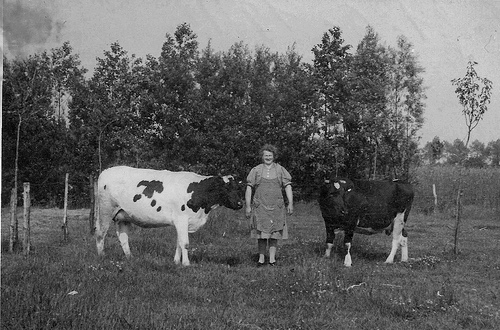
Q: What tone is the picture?
A: Black and white.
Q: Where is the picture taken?
A: A farm.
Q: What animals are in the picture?
A: Cows.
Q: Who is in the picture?
A: A woman.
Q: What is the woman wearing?
A: A dress.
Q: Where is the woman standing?
A: Between the cows.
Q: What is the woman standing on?
A: Grass.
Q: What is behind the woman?
A: Trees.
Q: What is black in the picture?
A: The right cow.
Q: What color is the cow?
A: Black and white.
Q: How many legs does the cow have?
A: Four.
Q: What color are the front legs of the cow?
A: White.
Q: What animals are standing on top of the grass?
A: Cows.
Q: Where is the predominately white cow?
A: Left of woman.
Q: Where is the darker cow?
A: Right side of woman.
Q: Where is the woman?
A: Between the cows.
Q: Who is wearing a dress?
A: The woman by the cows.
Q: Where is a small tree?
A: Right side of scene.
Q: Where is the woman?
A: Between the cows.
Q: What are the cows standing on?
A: Grass.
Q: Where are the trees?
A: Behind the woman.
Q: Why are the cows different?
A: They contain different colors and spots.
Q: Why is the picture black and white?
A: It's old.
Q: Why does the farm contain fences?
A: To protect animals from escaping.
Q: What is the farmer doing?
A: Posing for a picture.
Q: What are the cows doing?
A: Standing still.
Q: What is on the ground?
A: Grass.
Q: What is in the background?
A: Trees.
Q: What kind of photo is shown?
A: Black and white.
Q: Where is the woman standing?
A: Between two cows.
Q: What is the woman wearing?
A: A dress and an apron.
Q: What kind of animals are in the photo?
A: Cows.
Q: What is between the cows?
A: A woman.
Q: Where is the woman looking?
A: At the camera.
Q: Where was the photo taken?
A: In a field.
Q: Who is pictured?
A: A woman.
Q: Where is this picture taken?
A: A field.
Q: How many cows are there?
A: Two.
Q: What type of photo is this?
A: Black and white.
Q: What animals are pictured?
A: Cows.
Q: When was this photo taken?
A: Daytime.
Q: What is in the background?
A: Trees.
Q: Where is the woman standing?
A: Between the cows.